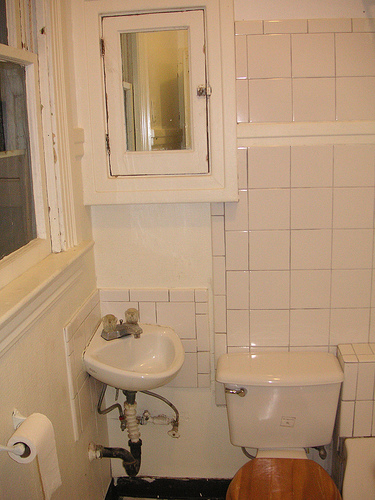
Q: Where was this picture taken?
A: A bathroom.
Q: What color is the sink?
A: White.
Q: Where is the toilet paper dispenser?
A: On the wall.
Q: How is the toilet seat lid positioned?
A: Down.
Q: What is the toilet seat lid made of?
A: Wood.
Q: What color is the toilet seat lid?
A: Brown.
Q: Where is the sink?
A: In the corner.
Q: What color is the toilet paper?
A: White.